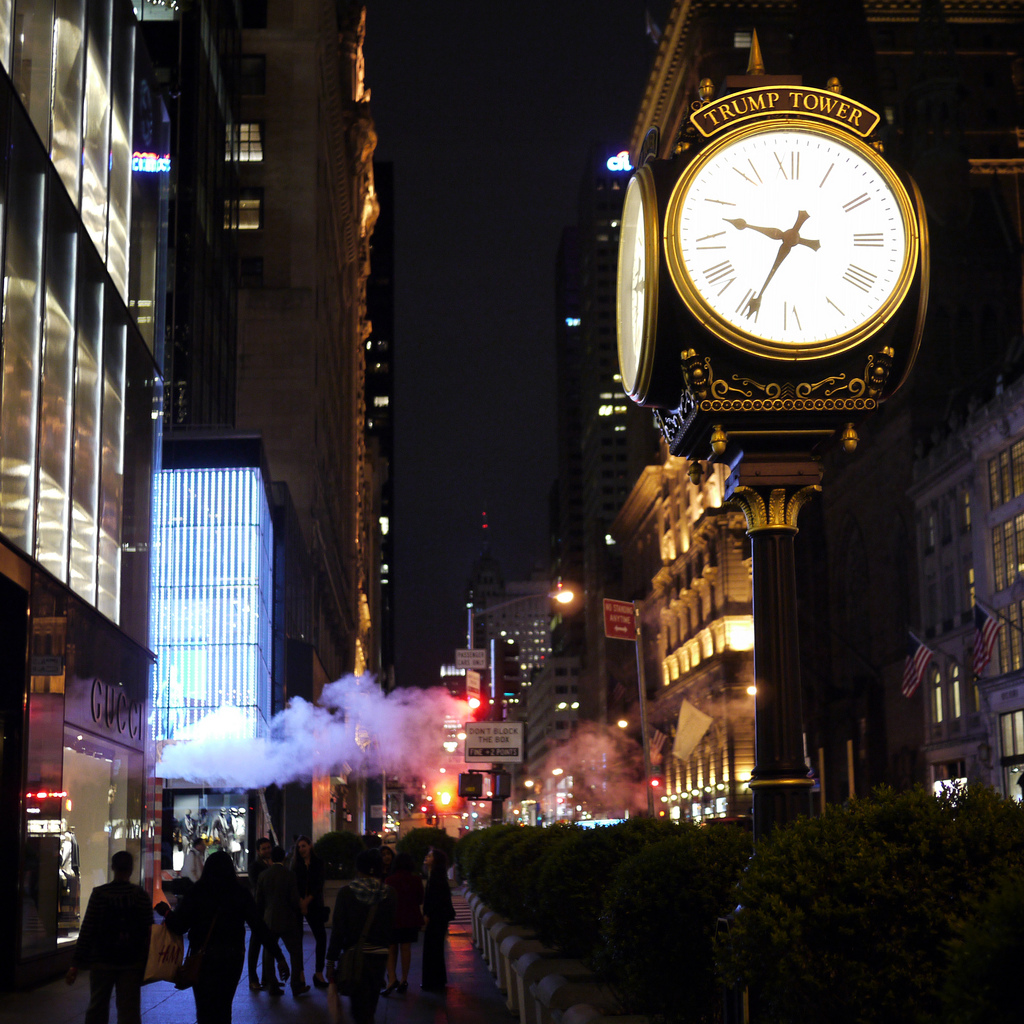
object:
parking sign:
[600, 592, 640, 642]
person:
[417, 840, 458, 999]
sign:
[462, 717, 527, 766]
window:
[97, 360, 127, 624]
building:
[164, 0, 375, 883]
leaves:
[701, 847, 718, 866]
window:
[714, 797, 728, 813]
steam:
[154, 668, 490, 792]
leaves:
[822, 896, 834, 915]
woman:
[323, 841, 400, 1022]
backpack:
[329, 880, 392, 997]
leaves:
[898, 852, 914, 868]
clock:
[605, 150, 663, 409]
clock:
[662, 109, 923, 366]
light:
[462, 692, 483, 715]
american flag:
[966, 603, 1007, 679]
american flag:
[895, 621, 935, 702]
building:
[905, 363, 1024, 814]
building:
[0, 0, 175, 992]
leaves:
[572, 912, 585, 931]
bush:
[457, 805, 1024, 1023]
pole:
[746, 508, 814, 881]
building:
[623, 0, 911, 829]